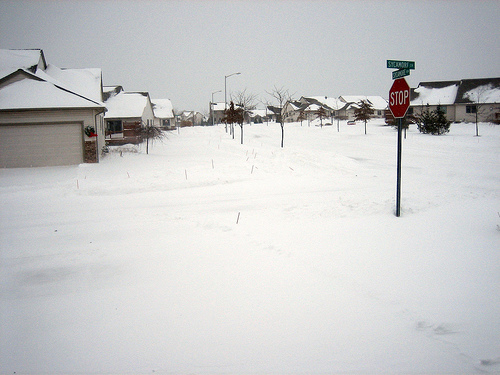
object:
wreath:
[83, 124, 99, 139]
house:
[0, 68, 109, 170]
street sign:
[386, 59, 417, 70]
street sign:
[391, 68, 411, 81]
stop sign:
[387, 76, 413, 120]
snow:
[49, 90, 53, 95]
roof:
[0, 66, 108, 108]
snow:
[127, 105, 141, 111]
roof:
[103, 85, 122, 94]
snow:
[423, 92, 453, 102]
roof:
[409, 80, 461, 106]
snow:
[327, 100, 339, 105]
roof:
[302, 95, 329, 104]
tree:
[263, 84, 299, 148]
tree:
[132, 119, 178, 155]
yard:
[0, 167, 500, 375]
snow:
[103, 234, 216, 283]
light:
[235, 70, 243, 78]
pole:
[223, 75, 229, 134]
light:
[216, 88, 224, 94]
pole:
[211, 93, 216, 131]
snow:
[331, 265, 444, 355]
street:
[0, 223, 500, 373]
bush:
[412, 103, 452, 136]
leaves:
[424, 110, 427, 113]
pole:
[395, 118, 403, 219]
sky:
[182, 11, 447, 36]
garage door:
[0, 120, 86, 170]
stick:
[233, 209, 244, 225]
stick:
[182, 166, 192, 184]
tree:
[350, 98, 382, 136]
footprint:
[415, 311, 458, 340]